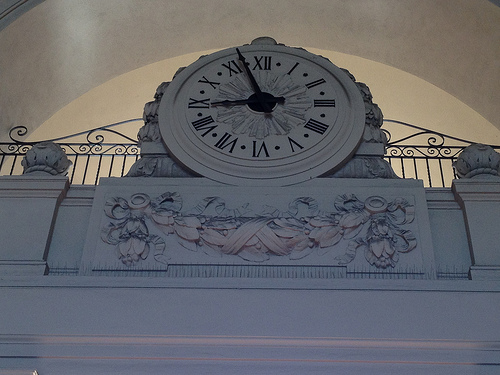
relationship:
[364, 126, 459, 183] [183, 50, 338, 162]
rail by face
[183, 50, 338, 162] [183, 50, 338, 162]
face belonging to face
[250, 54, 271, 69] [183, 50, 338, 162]
roman numeral painted on face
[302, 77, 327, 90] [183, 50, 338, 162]
roman numeral painted on face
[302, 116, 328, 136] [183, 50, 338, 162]
roman numeral painted on face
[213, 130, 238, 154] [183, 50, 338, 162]
roman numeral painted on face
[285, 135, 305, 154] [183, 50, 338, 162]
roman numeral painted on face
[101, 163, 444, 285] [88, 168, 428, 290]
painting on clock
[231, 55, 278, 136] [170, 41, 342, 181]
hands on clock